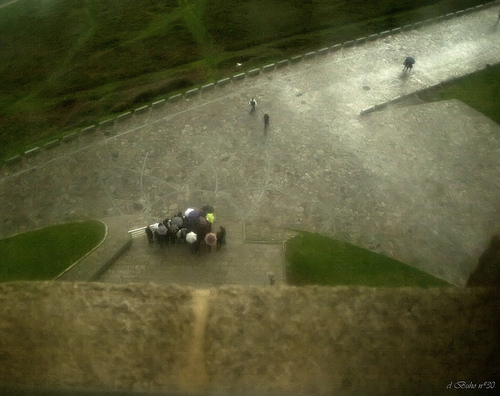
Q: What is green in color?
A: The grass.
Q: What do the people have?
A: Umbrellas.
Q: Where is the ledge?
A: Stone in the foreground.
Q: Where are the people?
A: On the pavement.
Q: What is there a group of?
A: Some people.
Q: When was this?
A: Daytime.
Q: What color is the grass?
A: Green.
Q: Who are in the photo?
A: People.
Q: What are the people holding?
A: Umbrellas.